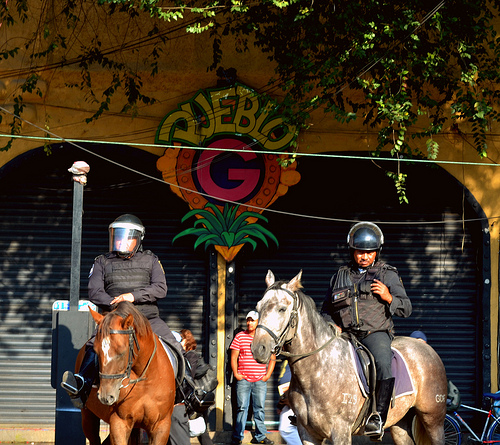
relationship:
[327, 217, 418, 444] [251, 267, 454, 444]
officer on horse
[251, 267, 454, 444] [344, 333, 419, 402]
horse has saddle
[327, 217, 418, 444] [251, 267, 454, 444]
officer riding horse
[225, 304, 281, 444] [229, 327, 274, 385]
man wearing shirt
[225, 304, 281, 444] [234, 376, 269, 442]
man wearing jeans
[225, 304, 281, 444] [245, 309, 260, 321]
man wearing hat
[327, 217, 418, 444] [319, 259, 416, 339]
officer wearing jacket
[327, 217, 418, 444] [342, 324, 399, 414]
officer wearing pants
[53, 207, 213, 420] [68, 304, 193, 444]
man on horse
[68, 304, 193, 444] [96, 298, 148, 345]
horse has mane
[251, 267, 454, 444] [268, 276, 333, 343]
horse has mane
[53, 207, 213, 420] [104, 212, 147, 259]
man wearing helmet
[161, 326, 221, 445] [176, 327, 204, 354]
person has hair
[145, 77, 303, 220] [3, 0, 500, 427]
sign attached to building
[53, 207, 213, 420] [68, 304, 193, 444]
man on top of horse